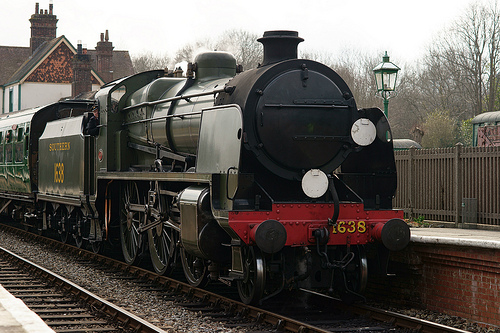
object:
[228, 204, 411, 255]
bumper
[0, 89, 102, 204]
train car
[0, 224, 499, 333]
tracks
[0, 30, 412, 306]
train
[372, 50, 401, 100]
light fixture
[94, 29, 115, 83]
chimney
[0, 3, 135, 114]
building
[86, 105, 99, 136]
person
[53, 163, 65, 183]
numbers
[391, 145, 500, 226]
fence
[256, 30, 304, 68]
smoke stack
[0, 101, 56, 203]
car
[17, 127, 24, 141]
window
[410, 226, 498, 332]
platform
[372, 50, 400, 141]
lamppost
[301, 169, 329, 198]
light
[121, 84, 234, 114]
pope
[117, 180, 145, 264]
wheel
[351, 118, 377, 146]
circle